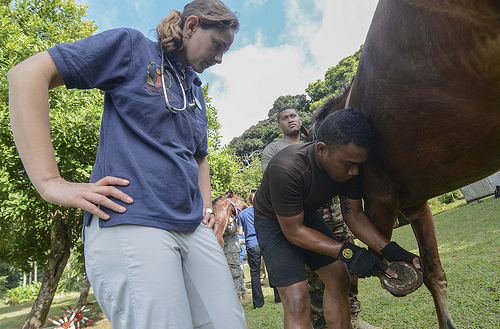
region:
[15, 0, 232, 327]
woman with hands on her hips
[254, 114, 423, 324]
man inspecting horse hoof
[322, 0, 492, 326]
big brown horse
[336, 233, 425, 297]
man with black gloves on hands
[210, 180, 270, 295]
horse with trainer in back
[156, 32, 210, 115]
stethoscope on woman's neck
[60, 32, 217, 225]
blue t-shirt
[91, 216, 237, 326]
woman has light grey pants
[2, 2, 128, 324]
tree behind woman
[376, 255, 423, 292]
bottom of horse hoof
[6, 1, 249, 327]
A woman wearing a stethascope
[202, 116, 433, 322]
A man pointing to the horse's hoof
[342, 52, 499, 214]
The side of the horse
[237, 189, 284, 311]
A woman with her back to the camera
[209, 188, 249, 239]
Part of a horse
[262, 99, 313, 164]
A man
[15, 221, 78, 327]
The trunk of a tree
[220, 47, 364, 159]
The tops of trees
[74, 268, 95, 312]
The trunk of a tree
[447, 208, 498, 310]
Some grass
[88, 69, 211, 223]
Woman is wearing a blue shirt.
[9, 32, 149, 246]
Woman's hand on her hip.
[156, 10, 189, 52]
Woman's hair is brown.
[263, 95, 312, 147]
Man is looking straight ahead.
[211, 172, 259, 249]
Horse and trainer in the background.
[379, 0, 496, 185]
Big brown horse.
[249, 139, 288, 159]
Man is wearing grey tshirt.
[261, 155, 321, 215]
Man is wearing brown tshirt.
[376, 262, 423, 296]
Horse shoe in man's hand.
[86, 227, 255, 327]
Woman is wearing light blue pants.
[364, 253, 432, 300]
the silver horse shoe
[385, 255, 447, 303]
the bottom of the horse's hoof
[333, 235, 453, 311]
man holding the horse's hoof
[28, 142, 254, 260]
woman's hands on her hips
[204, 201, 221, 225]
woman wearing a watch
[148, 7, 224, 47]
woman has a ponytail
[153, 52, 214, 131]
woman has a stethoscope around her neck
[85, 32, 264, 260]
woman is wearing a blue shirt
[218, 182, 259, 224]
horse is wearing a bridle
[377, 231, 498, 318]
horse standing in the grass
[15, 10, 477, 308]
doctor and man on side of horse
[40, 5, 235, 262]
woman with stethoscope around neck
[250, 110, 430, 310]
bent man lifting horse's foot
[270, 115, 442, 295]
man pointing at bottom of hoof with horseshoe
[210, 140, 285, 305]
woman standing next to horse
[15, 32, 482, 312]
people on green grass near trees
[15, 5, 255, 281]
doctor looking down with hands on hips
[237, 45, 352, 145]
tree tops behind man looking ahead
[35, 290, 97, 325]
orange and white spiky and round objects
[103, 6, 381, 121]
blue sky with thick white clouds